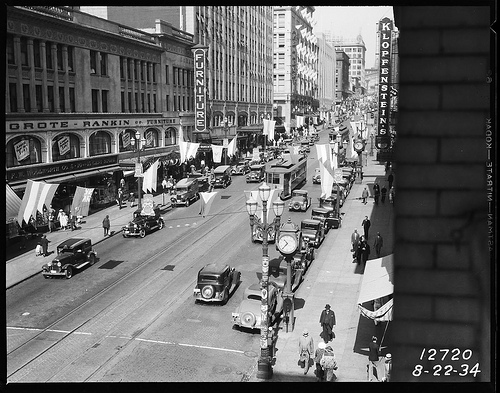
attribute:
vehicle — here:
[193, 249, 238, 315]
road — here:
[90, 122, 309, 326]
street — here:
[117, 210, 206, 375]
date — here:
[409, 352, 491, 371]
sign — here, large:
[15, 112, 163, 131]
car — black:
[40, 237, 106, 294]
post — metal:
[248, 197, 278, 378]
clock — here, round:
[264, 217, 316, 254]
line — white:
[46, 318, 285, 392]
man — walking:
[318, 298, 343, 330]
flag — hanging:
[360, 294, 397, 330]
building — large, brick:
[20, 62, 219, 161]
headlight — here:
[53, 257, 78, 284]